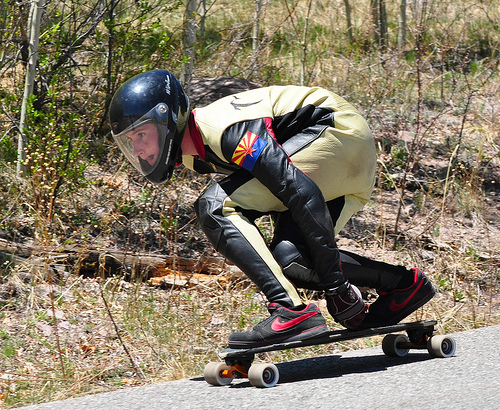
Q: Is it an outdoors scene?
A: Yes, it is outdoors.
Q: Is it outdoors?
A: Yes, it is outdoors.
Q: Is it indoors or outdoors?
A: It is outdoors.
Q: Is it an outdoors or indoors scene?
A: It is outdoors.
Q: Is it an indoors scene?
A: No, it is outdoors.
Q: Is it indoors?
A: No, it is outdoors.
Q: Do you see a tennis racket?
A: No, there are no rackets.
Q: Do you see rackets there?
A: No, there are no rackets.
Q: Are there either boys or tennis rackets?
A: No, there are no tennis rackets or boys.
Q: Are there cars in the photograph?
A: No, there are no cars.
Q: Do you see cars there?
A: No, there are no cars.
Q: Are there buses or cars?
A: No, there are no cars or buses.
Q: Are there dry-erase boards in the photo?
A: No, there are no dry-erase boards.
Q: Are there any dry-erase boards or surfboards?
A: No, there are no dry-erase boards or surfboards.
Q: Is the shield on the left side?
A: Yes, the shield is on the left of the image.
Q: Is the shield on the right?
A: No, the shield is on the left of the image.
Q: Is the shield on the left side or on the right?
A: The shield is on the left of the image.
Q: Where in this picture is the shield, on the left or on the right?
A: The shield is on the left of the image.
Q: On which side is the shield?
A: The shield is on the left of the image.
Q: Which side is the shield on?
A: The shield is on the left of the image.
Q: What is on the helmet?
A: The shield is on the helmet.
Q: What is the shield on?
A: The shield is on the helmet.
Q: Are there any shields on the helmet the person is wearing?
A: Yes, there is a shield on the helmet.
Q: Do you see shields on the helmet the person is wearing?
A: Yes, there is a shield on the helmet.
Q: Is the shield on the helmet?
A: Yes, the shield is on the helmet.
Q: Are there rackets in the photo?
A: No, there are no rackets.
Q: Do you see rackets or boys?
A: No, there are no rackets or boys.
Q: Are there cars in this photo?
A: No, there are no cars.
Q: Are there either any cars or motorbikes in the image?
A: No, there are no cars or motorbikes.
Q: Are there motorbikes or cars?
A: No, there are no cars or motorbikes.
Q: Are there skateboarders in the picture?
A: Yes, there is a skateboarder.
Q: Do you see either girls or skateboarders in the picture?
A: Yes, there is a skateboarder.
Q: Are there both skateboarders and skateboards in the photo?
A: Yes, there are both a skateboarder and a skateboard.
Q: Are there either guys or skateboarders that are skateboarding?
A: Yes, the skateboarder is skateboarding.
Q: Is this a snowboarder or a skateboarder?
A: This is a skateboarder.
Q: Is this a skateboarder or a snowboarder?
A: This is a skateboarder.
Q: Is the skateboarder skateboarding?
A: Yes, the skateboarder is skateboarding.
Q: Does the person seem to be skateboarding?
A: Yes, the skateboarder is skateboarding.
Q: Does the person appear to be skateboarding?
A: Yes, the skateboarder is skateboarding.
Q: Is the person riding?
A: No, the skateboarder is skateboarding.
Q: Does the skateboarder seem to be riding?
A: No, the skateboarder is skateboarding.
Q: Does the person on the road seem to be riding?
A: No, the skateboarder is skateboarding.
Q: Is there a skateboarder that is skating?
A: No, there is a skateboarder but he is skateboarding.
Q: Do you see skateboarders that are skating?
A: No, there is a skateboarder but he is skateboarding.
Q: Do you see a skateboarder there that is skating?
A: No, there is a skateboarder but he is skateboarding.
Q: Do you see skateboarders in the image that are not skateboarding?
A: No, there is a skateboarder but he is skateboarding.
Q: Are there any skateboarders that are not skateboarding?
A: No, there is a skateboarder but he is skateboarding.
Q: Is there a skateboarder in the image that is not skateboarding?
A: No, there is a skateboarder but he is skateboarding.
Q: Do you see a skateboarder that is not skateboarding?
A: No, there is a skateboarder but he is skateboarding.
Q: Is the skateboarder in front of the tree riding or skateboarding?
A: The skateboarder is skateboarding.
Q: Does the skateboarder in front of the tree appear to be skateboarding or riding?
A: The skateboarder is skateboarding.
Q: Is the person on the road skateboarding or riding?
A: The skateboarder is skateboarding.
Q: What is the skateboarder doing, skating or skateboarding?
A: The skateboarder is skateboarding.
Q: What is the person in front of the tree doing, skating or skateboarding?
A: The skateboarder is skateboarding.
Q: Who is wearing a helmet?
A: The skateboarder is wearing a helmet.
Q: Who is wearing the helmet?
A: The skateboarder is wearing a helmet.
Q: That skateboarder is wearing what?
A: The skateboarder is wearing a helmet.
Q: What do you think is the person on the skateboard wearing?
A: The skateboarder is wearing a helmet.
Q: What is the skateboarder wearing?
A: The skateboarder is wearing a helmet.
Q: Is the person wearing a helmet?
A: Yes, the skateboarder is wearing a helmet.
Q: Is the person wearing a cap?
A: No, the skateboarder is wearing a helmet.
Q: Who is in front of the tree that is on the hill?
A: The skateboarder is in front of the tree.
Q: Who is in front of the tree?
A: The skateboarder is in front of the tree.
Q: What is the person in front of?
A: The skateboarder is in front of the tree.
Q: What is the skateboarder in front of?
A: The skateboarder is in front of the tree.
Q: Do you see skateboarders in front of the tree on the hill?
A: Yes, there is a skateboarder in front of the tree.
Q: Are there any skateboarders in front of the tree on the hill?
A: Yes, there is a skateboarder in front of the tree.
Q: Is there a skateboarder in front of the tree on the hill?
A: Yes, there is a skateboarder in front of the tree.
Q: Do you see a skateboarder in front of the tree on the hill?
A: Yes, there is a skateboarder in front of the tree.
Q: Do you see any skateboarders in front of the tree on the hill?
A: Yes, there is a skateboarder in front of the tree.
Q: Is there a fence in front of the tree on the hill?
A: No, there is a skateboarder in front of the tree.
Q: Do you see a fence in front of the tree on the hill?
A: No, there is a skateboarder in front of the tree.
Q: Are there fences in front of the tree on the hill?
A: No, there is a skateboarder in front of the tree.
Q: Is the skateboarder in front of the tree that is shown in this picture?
A: Yes, the skateboarder is in front of the tree.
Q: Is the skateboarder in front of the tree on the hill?
A: Yes, the skateboarder is in front of the tree.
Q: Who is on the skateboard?
A: The skateboarder is on the skateboard.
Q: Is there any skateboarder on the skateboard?
A: Yes, there is a skateboarder on the skateboard.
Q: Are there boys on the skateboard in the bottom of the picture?
A: No, there is a skateboarder on the skateboard.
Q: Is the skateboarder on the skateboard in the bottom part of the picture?
A: Yes, the skateboarder is on the skateboard.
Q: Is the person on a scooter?
A: No, the skateboarder is on the skateboard.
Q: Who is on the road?
A: The skateboarder is on the road.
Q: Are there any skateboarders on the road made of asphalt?
A: Yes, there is a skateboarder on the road.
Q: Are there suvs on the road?
A: No, there is a skateboarder on the road.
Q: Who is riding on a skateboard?
A: The skateboarder is riding on a skateboard.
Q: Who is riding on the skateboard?
A: The skateboarder is riding on a skateboard.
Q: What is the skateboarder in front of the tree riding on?
A: The skateboarder is riding on a skateboard.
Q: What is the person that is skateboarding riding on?
A: The skateboarder is riding on a skateboard.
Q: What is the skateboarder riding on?
A: The skateboarder is riding on a skateboard.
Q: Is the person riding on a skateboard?
A: Yes, the skateboarder is riding on a skateboard.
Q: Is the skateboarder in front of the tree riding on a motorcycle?
A: No, the skateboarder is riding on a skateboard.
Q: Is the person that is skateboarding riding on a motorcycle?
A: No, the skateboarder is riding on a skateboard.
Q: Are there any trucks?
A: No, there are no trucks.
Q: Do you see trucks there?
A: No, there are no trucks.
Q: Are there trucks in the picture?
A: No, there are no trucks.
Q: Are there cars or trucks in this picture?
A: No, there are no trucks or cars.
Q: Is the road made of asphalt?
A: Yes, the road is made of asphalt.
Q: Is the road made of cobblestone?
A: No, the road is made of asphalt.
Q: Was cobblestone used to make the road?
A: No, the road is made of asphalt.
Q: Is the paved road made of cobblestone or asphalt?
A: The road is made of asphalt.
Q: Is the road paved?
A: Yes, the road is paved.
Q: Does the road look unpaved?
A: No, the road is paved.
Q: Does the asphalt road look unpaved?
A: No, the road is paved.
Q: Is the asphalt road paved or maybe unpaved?
A: The road is paved.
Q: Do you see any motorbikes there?
A: No, there are no motorbikes.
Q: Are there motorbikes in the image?
A: No, there are no motorbikes.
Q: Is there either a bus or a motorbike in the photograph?
A: No, there are no motorcycles or buses.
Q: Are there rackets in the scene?
A: No, there are no rackets.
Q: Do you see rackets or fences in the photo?
A: No, there are no rackets or fences.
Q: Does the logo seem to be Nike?
A: Yes, the logo is nike.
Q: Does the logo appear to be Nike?
A: Yes, the logo is nike.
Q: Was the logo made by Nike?
A: Yes, the logo was made by nike.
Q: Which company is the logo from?
A: The logo is from nike.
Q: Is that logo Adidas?
A: No, the logo is nike.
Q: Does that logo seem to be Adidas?
A: No, the logo is nike.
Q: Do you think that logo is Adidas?
A: No, the logo is nike.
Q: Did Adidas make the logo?
A: No, the logo was made by nike.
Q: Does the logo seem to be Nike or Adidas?
A: The logo is nike.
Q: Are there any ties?
A: No, there are no ties.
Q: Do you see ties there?
A: No, there are no ties.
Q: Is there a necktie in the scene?
A: No, there are no ties.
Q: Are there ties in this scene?
A: No, there are no ties.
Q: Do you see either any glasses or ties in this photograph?
A: No, there are no ties or glasses.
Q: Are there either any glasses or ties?
A: No, there are no ties or glasses.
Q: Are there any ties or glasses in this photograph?
A: No, there are no ties or glasses.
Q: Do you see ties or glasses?
A: No, there are no ties or glasses.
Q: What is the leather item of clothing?
A: The clothing item is a suit.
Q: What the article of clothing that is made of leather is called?
A: The clothing item is a suit.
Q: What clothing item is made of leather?
A: The clothing item is a suit.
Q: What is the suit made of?
A: The suit is made of leather.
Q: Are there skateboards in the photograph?
A: Yes, there is a skateboard.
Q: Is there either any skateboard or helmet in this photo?
A: Yes, there is a skateboard.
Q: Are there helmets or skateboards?
A: Yes, there is a skateboard.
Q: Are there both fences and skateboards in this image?
A: No, there is a skateboard but no fences.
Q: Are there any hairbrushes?
A: No, there are no hairbrushes.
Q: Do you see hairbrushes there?
A: No, there are no hairbrushes.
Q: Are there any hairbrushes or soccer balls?
A: No, there are no hairbrushes or soccer balls.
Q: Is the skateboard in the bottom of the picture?
A: Yes, the skateboard is in the bottom of the image.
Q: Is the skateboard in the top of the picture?
A: No, the skateboard is in the bottom of the image.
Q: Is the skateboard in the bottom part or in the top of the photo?
A: The skateboard is in the bottom of the image.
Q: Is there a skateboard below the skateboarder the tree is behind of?
A: Yes, there is a skateboard below the skateboarder.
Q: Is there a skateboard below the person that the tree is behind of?
A: Yes, there is a skateboard below the skateboarder.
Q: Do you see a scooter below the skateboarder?
A: No, there is a skateboard below the skateboarder.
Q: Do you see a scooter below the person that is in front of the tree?
A: No, there is a skateboard below the skateboarder.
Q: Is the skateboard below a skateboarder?
A: Yes, the skateboard is below a skateboarder.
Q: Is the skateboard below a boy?
A: No, the skateboard is below a skateboarder.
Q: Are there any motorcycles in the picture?
A: No, there are no motorcycles.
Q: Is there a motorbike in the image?
A: No, there are no motorcycles.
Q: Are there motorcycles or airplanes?
A: No, there are no motorcycles or airplanes.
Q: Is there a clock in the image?
A: No, there are no clocks.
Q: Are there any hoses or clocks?
A: No, there are no clocks or hoses.